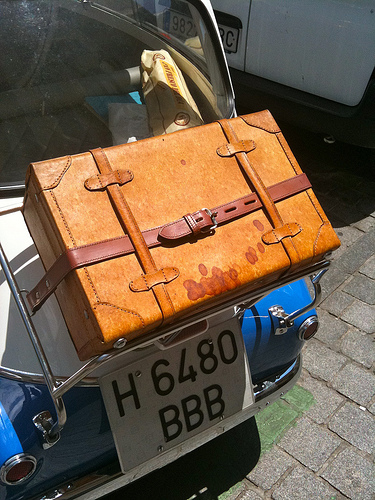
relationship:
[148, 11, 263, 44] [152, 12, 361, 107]
license plate on car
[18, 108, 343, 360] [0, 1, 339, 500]
suitcase strapped to blue car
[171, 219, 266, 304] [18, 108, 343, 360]
stains on suitcase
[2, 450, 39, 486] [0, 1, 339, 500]
lights of blue car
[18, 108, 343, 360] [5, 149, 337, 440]
suitcase strapped to trunk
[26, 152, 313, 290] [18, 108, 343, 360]
leather strap across suitcase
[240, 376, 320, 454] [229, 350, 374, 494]
green spot on ground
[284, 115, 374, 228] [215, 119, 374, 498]
shadow on ground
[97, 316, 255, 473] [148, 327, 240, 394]
license plate has numbers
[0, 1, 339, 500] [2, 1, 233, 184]
blue car has glass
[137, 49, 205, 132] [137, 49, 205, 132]
bag has bag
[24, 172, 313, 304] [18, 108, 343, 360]
leather strap holding suitcase